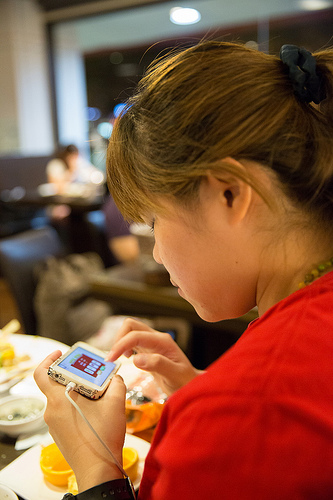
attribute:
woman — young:
[30, 34, 332, 500]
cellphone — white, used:
[43, 336, 127, 406]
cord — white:
[61, 379, 142, 497]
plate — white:
[2, 420, 154, 499]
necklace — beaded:
[287, 258, 332, 292]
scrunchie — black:
[273, 38, 326, 110]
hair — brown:
[102, 35, 333, 232]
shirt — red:
[130, 259, 333, 499]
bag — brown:
[26, 251, 114, 344]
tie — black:
[276, 35, 326, 106]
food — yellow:
[0, 313, 35, 379]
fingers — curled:
[102, 313, 180, 383]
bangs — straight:
[97, 108, 165, 226]